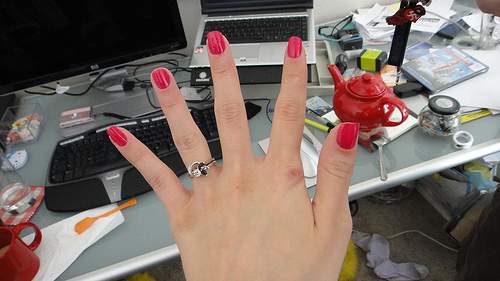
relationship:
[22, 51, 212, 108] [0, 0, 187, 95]
black cords behind monitor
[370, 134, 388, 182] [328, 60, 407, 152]
spoon next to teapot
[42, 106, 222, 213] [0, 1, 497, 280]
keyboard on desk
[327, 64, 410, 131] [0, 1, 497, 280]
kettle on desk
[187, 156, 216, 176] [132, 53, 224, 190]
ring on finger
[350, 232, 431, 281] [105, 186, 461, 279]
sock on floor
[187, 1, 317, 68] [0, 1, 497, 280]
computer on desk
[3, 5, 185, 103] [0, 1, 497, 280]
monitor on desk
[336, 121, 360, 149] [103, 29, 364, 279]
nail on hand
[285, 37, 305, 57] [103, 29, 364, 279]
nail on hand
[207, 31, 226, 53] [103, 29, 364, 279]
nail on hand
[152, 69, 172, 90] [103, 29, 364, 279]
nail on hand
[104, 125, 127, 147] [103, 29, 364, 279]
fingernails on hand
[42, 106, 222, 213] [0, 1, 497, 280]
keyboard on top of desk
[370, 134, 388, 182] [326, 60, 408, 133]
spoon next to tea pot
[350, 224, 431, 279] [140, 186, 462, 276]
sock on floor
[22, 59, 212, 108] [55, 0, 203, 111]
black cords behind monitor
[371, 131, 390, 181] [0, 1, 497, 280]
spoon on top of desk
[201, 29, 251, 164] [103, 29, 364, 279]
finger on hand